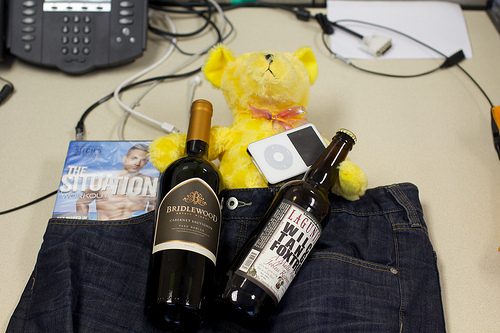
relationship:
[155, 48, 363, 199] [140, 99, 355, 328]
teddy bear next to bottles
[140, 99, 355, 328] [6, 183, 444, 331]
wine bottles on jeans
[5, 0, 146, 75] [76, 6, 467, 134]
telephone next to cables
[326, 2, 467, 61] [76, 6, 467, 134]
paper under cables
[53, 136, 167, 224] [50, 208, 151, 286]
dvd case in jeans pocket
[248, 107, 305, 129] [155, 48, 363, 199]
bow tie on teddy bear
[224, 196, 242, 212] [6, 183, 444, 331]
button on jeans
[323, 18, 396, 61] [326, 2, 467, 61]
cable on top of paper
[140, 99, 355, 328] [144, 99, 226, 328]
bottles of wine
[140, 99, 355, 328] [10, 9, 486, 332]
bottles on table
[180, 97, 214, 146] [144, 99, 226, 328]
wrapping on wine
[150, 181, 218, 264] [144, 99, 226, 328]
label on bottle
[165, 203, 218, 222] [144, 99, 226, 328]
writing on wine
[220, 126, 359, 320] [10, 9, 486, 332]
bottle on table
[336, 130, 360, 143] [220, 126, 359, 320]
cap on beer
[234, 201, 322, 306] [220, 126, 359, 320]
label on bottle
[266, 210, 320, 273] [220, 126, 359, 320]
writing on bottle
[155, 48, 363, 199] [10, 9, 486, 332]
teddy bear on table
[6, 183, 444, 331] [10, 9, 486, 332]
jeans on table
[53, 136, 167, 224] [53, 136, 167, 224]
dvd in dvd case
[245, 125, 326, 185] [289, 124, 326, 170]
ipod has a dark screen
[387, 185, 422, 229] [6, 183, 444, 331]
belt loop in on jeans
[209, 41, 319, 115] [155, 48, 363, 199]
head of teddy bear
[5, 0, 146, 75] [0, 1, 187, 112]
telephone in upper left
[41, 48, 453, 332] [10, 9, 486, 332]
items laid out on a desk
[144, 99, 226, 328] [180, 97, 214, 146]
bottle with gold colored top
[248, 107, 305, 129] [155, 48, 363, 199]
bow tie attached to teddy bear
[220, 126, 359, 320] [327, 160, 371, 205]
bottle next to bears paw